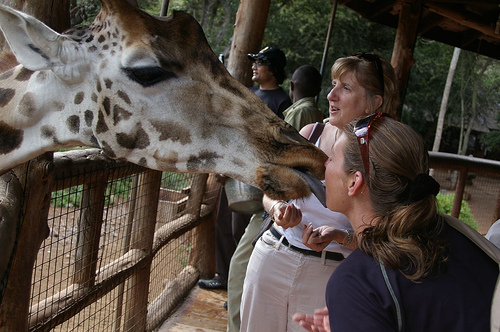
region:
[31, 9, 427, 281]
the giraffe is licking the lady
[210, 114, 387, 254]
the giraffe's tongue is grey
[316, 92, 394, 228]
the lady has sunglasses on her head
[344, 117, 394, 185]
the sunglasses are red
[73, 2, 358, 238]
the giraffe looks friendly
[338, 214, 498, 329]
the lady is wearing a dark blue shirt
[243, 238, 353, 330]
the other lady is wearing white pants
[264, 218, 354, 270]
she has on a black belt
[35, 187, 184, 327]
a fence is separating the giraffe from the people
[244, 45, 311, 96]
the man is wearing a cap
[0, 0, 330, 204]
a brown and white giraffe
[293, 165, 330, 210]
a long blue tongue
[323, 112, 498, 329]
a women with her eyes close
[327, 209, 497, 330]
a women with a blue blouse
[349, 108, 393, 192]
a pair of brown sunglasses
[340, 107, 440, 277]
a women with blonde hair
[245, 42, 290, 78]
a man wearing a black hat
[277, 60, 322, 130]
a man with a gray shirt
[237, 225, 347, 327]
a women wearing white pants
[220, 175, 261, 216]
a gray tin bucket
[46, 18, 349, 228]
a giraffe sticking its tongue out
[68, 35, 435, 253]
a giraffe licking a woman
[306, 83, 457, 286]
a woman with sunglasses on her head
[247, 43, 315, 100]
a man with glasses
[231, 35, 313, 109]
a man with a hat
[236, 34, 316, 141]
a man with a hat and glasses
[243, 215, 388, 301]
a black belt and white pants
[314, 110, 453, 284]
a brunette woman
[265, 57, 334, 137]
a african american male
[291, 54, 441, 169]
a white woman with a white tank top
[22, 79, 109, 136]
brown spots on a giraffe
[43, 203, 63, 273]
a wood and wire mesh fence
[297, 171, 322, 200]
a long black tongue touching a face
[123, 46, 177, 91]
a black eye on a head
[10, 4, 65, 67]
a pointy ear on a head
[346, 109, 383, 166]
sunglasses on top of a head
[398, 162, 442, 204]
a black scrunchie in her hair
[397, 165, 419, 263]
a long brown ponytail on a head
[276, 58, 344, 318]
a woman holding feed in her hands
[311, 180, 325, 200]
tongue of a giraffe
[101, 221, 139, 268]
part of a meshed fence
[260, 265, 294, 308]
part of a white trouser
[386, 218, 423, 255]
hair of a woman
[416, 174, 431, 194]
part of a black band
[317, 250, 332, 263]
section of a belt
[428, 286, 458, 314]
part of a dark top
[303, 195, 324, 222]
part of a white top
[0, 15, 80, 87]
right ear of a giraffe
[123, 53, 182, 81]
right eye of a giraffe